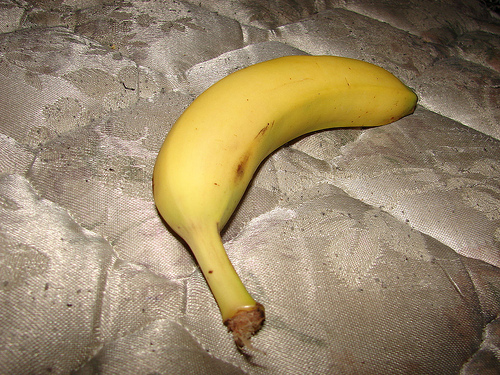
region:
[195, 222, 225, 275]
part of a banaan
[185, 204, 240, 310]
par tof a pell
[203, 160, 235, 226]
edge of a peel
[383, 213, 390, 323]
part of a sheet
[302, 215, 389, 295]
this is a couch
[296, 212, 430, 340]
the couch is white in color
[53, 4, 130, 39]
drawing of a flower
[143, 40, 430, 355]
this is a banana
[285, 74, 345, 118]
the banana is yellow in color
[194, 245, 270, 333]
this is the stalk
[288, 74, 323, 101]
the banana is clean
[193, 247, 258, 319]
the stalk is big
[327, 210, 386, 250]
the drawing is small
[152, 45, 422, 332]
single banana is on cover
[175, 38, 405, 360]
color of banana is yellow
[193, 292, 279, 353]
end of banana is brown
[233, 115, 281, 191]
brown spots on the banana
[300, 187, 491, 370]
bed covering is quilted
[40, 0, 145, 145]
gray design on bed covering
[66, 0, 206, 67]
flowers and stems on bed cover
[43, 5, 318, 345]
banana lying on quilt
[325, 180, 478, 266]
creases in the bed cover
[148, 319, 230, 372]
stitching inside the covering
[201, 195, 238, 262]
edge of a peel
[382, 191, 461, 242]
part f a lne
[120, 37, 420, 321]
banana on a bed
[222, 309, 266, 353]
The brown stem top of the banana.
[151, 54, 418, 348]
A curved yellow banana.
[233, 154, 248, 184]
The longest darkest brown rot on the banana.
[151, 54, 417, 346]
A yellow banana lying on a bed.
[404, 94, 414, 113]
Green hew on the end of the banana opposite of the stem.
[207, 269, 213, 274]
Small round brown mark on the thin banana stem.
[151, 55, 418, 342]
A curved yellow banana lying on a bed.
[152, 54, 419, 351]
A bruised yellow banana on a bed.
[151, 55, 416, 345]
A semi-bruised yellow banana on a bed.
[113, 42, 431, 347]
banana on the bed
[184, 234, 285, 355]
top of the banana